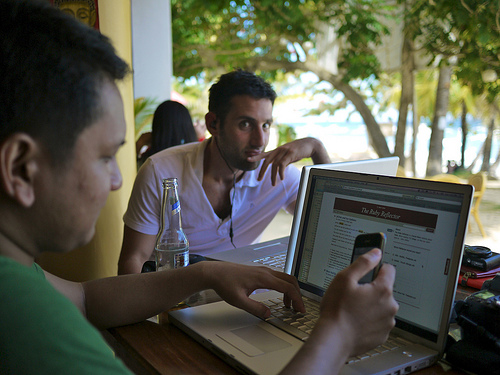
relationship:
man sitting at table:
[0, 1, 401, 373] [110, 258, 498, 374]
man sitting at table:
[118, 71, 331, 275] [110, 258, 498, 374]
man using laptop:
[0, 1, 401, 373] [171, 167, 474, 372]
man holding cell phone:
[0, 1, 401, 373] [350, 230, 386, 285]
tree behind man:
[174, 1, 393, 159] [118, 71, 331, 275]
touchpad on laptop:
[232, 323, 292, 353] [171, 167, 474, 372]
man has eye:
[118, 71, 331, 275] [239, 120, 250, 128]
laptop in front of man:
[171, 167, 474, 372] [0, 1, 401, 373]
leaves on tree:
[338, 49, 382, 84] [174, 1, 393, 159]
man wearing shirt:
[118, 71, 331, 275] [124, 137, 301, 248]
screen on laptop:
[294, 174, 462, 344] [171, 167, 474, 372]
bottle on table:
[156, 177, 191, 310] [110, 258, 498, 374]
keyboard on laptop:
[251, 296, 396, 362] [171, 167, 474, 372]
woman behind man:
[134, 99, 199, 165] [118, 71, 331, 275]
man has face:
[0, 1, 401, 373] [69, 81, 126, 257]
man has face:
[118, 71, 331, 275] [222, 94, 275, 173]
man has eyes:
[118, 71, 331, 275] [238, 118, 272, 131]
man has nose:
[118, 71, 331, 275] [250, 127, 267, 149]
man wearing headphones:
[118, 71, 331, 275] [208, 119, 243, 248]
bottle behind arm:
[156, 177, 191, 310] [45, 261, 308, 326]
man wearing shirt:
[0, 1, 401, 373] [1, 258, 133, 372]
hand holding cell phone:
[319, 247, 400, 356] [350, 230, 386, 285]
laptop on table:
[171, 167, 474, 372] [110, 258, 498, 374]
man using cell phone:
[0, 1, 401, 373] [350, 230, 386, 285]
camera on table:
[447, 296, 499, 374] [110, 258, 498, 374]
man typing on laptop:
[0, 1, 401, 373] [171, 167, 474, 372]